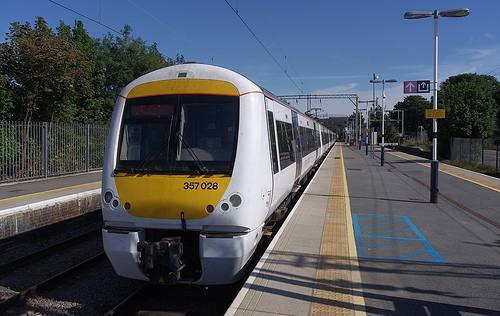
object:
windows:
[115, 92, 240, 175]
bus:
[98, 62, 340, 286]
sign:
[402, 79, 431, 93]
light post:
[429, 18, 439, 203]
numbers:
[212, 182, 219, 190]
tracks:
[0, 250, 240, 314]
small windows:
[274, 118, 297, 172]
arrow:
[404, 81, 415, 92]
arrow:
[421, 82, 427, 88]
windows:
[297, 124, 318, 158]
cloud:
[287, 81, 431, 115]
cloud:
[434, 47, 480, 77]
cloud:
[386, 61, 431, 72]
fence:
[0, 119, 109, 182]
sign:
[425, 108, 446, 118]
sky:
[2, 0, 499, 115]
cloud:
[279, 72, 369, 79]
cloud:
[462, 35, 477, 47]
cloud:
[252, 67, 281, 77]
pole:
[431, 26, 451, 189]